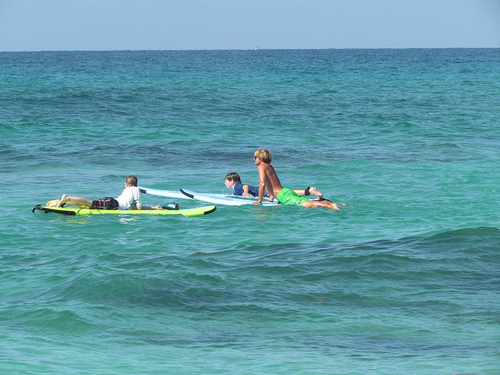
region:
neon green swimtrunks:
[271, 181, 313, 213]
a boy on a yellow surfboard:
[36, 160, 221, 230]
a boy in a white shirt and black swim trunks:
[43, 149, 150, 212]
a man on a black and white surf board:
[175, 132, 345, 222]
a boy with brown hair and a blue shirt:
[213, 158, 269, 200]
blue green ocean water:
[378, 161, 491, 234]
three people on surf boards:
[34, 117, 351, 259]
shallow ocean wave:
[81, 222, 498, 309]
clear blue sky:
[4, 0, 499, 48]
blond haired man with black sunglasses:
[249, 146, 280, 168]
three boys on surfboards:
[38, 142, 344, 235]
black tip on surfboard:
[179, 189, 194, 201]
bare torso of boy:
[257, 162, 282, 196]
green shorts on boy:
[278, 182, 315, 206]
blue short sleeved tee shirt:
[231, 179, 261, 199]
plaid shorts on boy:
[84, 195, 121, 215]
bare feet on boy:
[45, 192, 68, 212]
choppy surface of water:
[303, 98, 428, 168]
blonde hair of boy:
[253, 144, 272, 165]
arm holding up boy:
[249, 174, 266, 211]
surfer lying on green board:
[28, 165, 215, 230]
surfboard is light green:
[33, 201, 220, 228]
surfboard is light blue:
[180, 185, 282, 212]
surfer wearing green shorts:
[253, 140, 343, 221]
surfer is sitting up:
[253, 130, 352, 219]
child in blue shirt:
[216, 161, 308, 203]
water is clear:
[31, 72, 499, 340]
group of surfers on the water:
[39, 132, 405, 225]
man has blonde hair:
[248, 144, 346, 216]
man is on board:
[251, 146, 338, 238]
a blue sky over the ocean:
[1, 0, 499, 46]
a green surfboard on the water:
[32, 204, 217, 218]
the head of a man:
[121, 172, 140, 189]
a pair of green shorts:
[275, 183, 308, 209]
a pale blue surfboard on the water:
[176, 185, 313, 208]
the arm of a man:
[251, 163, 267, 208]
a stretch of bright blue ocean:
[1, 48, 499, 373]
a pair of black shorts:
[88, 192, 118, 214]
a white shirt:
[116, 184, 141, 213]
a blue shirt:
[232, 181, 271, 200]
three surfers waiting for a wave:
[33, 145, 341, 216]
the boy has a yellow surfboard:
[30, 185, 213, 220]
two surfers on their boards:
[140, 145, 341, 206]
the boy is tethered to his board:
[140, 166, 325, 201]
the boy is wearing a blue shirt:
[222, 170, 264, 198]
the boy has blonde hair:
[247, 141, 270, 166]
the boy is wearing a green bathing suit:
[250, 146, 310, 208]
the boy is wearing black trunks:
[86, 176, 138, 216]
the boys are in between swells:
[7, 137, 497, 308]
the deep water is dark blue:
[2, 27, 499, 75]